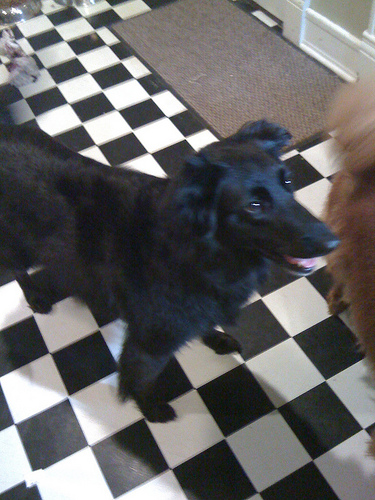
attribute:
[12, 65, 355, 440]
dog — black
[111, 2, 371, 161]
doormat — brown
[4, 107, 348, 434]
dog — black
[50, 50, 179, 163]
tiles — black, white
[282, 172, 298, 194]
eye — black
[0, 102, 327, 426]
dog — black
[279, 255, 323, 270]
tongue — pink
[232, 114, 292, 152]
ears — black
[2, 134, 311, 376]
dog — standing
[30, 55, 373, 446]
dog' — black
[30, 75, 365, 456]
dog — black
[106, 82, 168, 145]
square — black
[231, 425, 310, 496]
square — black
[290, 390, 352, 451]
square — white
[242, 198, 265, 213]
eye — black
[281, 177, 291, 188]
eye — black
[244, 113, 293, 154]
ear — black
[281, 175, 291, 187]
dogeye — black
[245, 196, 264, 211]
dogeye — black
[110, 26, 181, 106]
edges — black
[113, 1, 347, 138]
mat — brown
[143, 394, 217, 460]
square — white, black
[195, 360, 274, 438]
square — black, brown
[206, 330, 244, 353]
paw — black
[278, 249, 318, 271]
tongue — pink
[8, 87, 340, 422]
dog — black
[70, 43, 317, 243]
rug — brown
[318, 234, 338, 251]
nose — black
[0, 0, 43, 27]
dish — metal, dog, silver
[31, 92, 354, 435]
dog — black